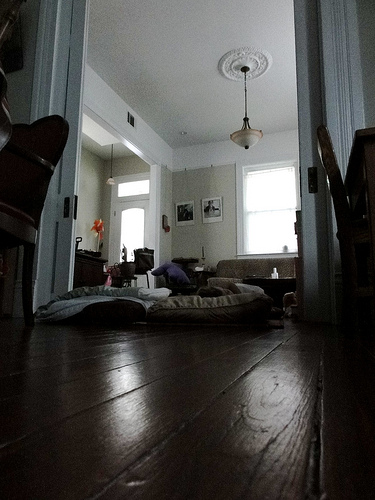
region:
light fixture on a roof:
[204, 32, 288, 169]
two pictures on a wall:
[165, 194, 235, 235]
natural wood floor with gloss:
[56, 356, 276, 491]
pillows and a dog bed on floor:
[35, 233, 265, 337]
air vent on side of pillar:
[115, 102, 147, 135]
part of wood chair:
[0, 93, 81, 335]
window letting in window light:
[221, 157, 298, 276]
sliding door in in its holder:
[271, 40, 338, 334]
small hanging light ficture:
[97, 137, 120, 197]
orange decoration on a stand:
[88, 204, 114, 262]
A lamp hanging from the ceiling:
[225, 54, 277, 160]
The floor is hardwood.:
[69, 347, 308, 471]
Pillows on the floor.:
[78, 276, 264, 331]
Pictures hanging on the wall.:
[166, 186, 244, 229]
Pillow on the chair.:
[149, 253, 190, 287]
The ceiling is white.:
[137, 26, 215, 128]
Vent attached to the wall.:
[118, 107, 143, 136]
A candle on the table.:
[194, 235, 210, 271]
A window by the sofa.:
[226, 161, 307, 257]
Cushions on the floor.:
[145, 273, 263, 330]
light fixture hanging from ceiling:
[229, 61, 267, 151]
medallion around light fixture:
[215, 45, 273, 83]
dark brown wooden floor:
[3, 318, 374, 498]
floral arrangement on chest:
[88, 216, 107, 252]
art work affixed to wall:
[172, 198, 225, 225]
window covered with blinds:
[238, 163, 300, 255]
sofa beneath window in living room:
[205, 256, 299, 291]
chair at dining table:
[0, 110, 74, 318]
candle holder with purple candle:
[199, 245, 209, 270]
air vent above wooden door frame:
[120, 107, 140, 134]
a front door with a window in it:
[115, 202, 149, 289]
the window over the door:
[118, 180, 149, 195]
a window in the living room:
[244, 162, 294, 251]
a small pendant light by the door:
[106, 145, 117, 185]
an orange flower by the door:
[91, 218, 103, 250]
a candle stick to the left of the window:
[199, 246, 206, 269]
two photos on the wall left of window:
[175, 196, 222, 227]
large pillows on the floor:
[37, 285, 273, 319]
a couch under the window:
[207, 258, 296, 288]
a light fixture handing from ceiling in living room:
[231, 66, 262, 150]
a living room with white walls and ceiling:
[2, 2, 368, 499]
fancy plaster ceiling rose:
[214, 46, 276, 83]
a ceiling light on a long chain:
[227, 61, 265, 153]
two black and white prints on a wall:
[171, 194, 225, 226]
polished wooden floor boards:
[2, 314, 335, 497]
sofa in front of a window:
[203, 161, 299, 301]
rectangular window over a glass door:
[109, 175, 150, 282]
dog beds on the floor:
[37, 275, 268, 329]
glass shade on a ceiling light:
[228, 123, 268, 151]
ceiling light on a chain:
[103, 141, 119, 188]